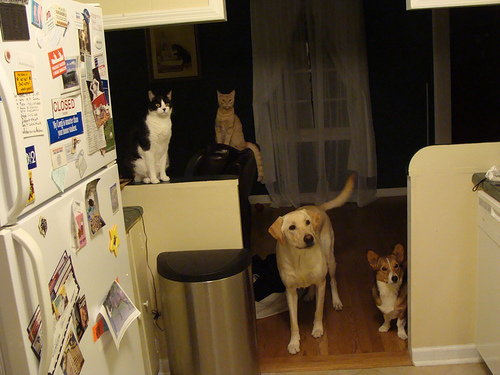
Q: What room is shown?
A: It is a kitchen.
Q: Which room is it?
A: It is a kitchen.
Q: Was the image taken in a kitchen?
A: Yes, it was taken in a kitchen.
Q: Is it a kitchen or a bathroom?
A: It is a kitchen.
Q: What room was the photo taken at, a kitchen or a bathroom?
A: It was taken at a kitchen.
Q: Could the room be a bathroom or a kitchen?
A: It is a kitchen.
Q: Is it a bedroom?
A: No, it is a kitchen.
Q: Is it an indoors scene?
A: Yes, it is indoors.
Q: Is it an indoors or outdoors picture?
A: It is indoors.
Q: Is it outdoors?
A: No, it is indoors.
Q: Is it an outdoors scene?
A: No, it is indoors.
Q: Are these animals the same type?
A: No, there are both dogs and cats.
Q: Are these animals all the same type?
A: No, there are both dogs and cats.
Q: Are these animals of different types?
A: Yes, they are dogs and cats.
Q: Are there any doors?
A: Yes, there is a door.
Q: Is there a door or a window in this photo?
A: Yes, there is a door.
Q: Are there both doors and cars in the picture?
A: No, there is a door but no cars.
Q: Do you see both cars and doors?
A: No, there is a door but no cars.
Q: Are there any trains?
A: No, there are no trains.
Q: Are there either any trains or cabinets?
A: No, there are no trains or cabinets.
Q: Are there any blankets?
A: No, there are no blankets.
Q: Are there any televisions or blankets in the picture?
A: No, there are no blankets or televisions.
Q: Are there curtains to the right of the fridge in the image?
A: Yes, there are curtains to the right of the fridge.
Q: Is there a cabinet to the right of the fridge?
A: No, there are curtains to the right of the fridge.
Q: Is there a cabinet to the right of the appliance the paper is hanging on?
A: No, there are curtains to the right of the fridge.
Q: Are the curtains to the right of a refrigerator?
A: Yes, the curtains are to the right of a refrigerator.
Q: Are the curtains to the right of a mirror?
A: No, the curtains are to the right of a refrigerator.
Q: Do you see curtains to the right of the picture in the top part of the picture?
A: Yes, there are curtains to the right of the picture.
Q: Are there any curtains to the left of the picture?
A: No, the curtains are to the right of the picture.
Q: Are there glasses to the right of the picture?
A: No, there are curtains to the right of the picture.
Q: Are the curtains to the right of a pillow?
A: No, the curtains are to the right of the picture.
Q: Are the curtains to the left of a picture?
A: No, the curtains are to the right of a picture.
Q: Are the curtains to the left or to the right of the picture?
A: The curtains are to the right of the picture.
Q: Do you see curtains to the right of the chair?
A: Yes, there are curtains to the right of the chair.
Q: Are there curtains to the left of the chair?
A: No, the curtains are to the right of the chair.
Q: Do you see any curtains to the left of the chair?
A: No, the curtains are to the right of the chair.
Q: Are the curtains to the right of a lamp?
A: No, the curtains are to the right of a chair.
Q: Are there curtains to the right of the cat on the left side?
A: Yes, there are curtains to the right of the cat.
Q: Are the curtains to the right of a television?
A: No, the curtains are to the right of a cat.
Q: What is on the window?
A: The curtains are on the window.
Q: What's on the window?
A: The curtains are on the window.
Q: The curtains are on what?
A: The curtains are on the window.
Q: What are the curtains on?
A: The curtains are on the window.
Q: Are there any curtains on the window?
A: Yes, there are curtains on the window.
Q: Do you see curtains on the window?
A: Yes, there are curtains on the window.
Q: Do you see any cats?
A: Yes, there is a cat.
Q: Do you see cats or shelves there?
A: Yes, there is a cat.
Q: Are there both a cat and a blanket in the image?
A: No, there is a cat but no blankets.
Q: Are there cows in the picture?
A: No, there are no cows.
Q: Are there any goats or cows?
A: No, there are no cows or goats.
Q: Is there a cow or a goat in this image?
A: No, there are no cows or goats.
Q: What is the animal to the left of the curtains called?
A: The animal is a cat.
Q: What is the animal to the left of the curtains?
A: The animal is a cat.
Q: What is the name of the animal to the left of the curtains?
A: The animal is a cat.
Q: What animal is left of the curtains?
A: The animal is a cat.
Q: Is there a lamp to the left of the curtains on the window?
A: No, there is a cat to the left of the curtains.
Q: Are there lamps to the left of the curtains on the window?
A: No, there is a cat to the left of the curtains.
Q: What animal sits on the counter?
A: The cat sits on the counter.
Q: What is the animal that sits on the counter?
A: The animal is a cat.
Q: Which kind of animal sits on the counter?
A: The animal is a cat.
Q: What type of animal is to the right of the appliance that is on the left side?
A: The animal is a cat.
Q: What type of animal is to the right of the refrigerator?
A: The animal is a cat.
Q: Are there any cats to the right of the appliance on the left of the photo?
A: Yes, there is a cat to the right of the fridge.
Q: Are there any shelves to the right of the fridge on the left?
A: No, there is a cat to the right of the freezer.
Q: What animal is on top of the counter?
A: The animal is a cat.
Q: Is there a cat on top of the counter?
A: Yes, there is a cat on top of the counter.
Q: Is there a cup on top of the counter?
A: No, there is a cat on top of the counter.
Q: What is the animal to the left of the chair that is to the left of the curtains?
A: The animal is a cat.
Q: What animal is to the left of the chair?
A: The animal is a cat.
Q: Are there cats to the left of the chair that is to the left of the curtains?
A: Yes, there is a cat to the left of the chair.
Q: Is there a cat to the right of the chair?
A: No, the cat is to the left of the chair.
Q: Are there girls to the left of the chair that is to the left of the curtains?
A: No, there is a cat to the left of the chair.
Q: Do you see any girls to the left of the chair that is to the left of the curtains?
A: No, there is a cat to the left of the chair.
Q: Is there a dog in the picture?
A: Yes, there is a dog.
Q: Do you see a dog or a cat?
A: Yes, there is a dog.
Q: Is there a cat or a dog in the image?
A: Yes, there is a dog.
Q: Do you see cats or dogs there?
A: Yes, there is a dog.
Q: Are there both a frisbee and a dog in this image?
A: No, there is a dog but no frisbees.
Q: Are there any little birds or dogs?
A: Yes, there is a little dog.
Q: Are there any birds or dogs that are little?
A: Yes, the dog is little.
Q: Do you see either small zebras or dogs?
A: Yes, there is a small dog.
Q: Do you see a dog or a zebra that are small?
A: Yes, the dog is small.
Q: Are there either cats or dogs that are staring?
A: Yes, the dog is staring.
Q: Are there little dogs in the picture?
A: Yes, there is a little dog.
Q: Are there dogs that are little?
A: Yes, there is a dog that is little.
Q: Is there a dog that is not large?
A: Yes, there is a little dog.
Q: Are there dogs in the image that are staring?
A: Yes, there is a dog that is staring.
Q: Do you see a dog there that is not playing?
A: Yes, there is a dog that is staring .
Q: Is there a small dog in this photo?
A: Yes, there is a small dog.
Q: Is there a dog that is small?
A: Yes, there is a dog that is small.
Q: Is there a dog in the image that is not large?
A: Yes, there is a small dog.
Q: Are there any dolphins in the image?
A: No, there are no dolphins.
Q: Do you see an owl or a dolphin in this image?
A: No, there are no dolphins or owls.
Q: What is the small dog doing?
A: The dog is staring.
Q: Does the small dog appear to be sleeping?
A: No, the dog is staring.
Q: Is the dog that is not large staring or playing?
A: The dog is staring.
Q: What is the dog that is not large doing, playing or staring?
A: The dog is staring.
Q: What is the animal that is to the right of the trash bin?
A: The animal is a dog.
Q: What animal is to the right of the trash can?
A: The animal is a dog.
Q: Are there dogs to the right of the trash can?
A: Yes, there is a dog to the right of the trash can.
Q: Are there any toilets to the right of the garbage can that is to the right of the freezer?
A: No, there is a dog to the right of the garbage bin.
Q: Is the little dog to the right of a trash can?
A: Yes, the dog is to the right of a trash can.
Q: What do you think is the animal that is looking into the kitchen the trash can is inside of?
A: The animal is a dog.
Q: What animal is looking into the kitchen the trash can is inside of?
A: The animal is a dog.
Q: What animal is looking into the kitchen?
A: The animal is a dog.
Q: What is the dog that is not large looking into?
A: The dog is looking into the kitchen.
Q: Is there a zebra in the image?
A: No, there are no zebras.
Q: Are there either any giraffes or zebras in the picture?
A: No, there are no zebras or giraffes.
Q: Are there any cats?
A: Yes, there is a cat.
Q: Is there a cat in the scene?
A: Yes, there is a cat.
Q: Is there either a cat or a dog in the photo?
A: Yes, there is a cat.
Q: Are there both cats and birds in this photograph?
A: No, there is a cat but no birds.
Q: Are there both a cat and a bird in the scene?
A: No, there is a cat but no birds.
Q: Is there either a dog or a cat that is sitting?
A: Yes, the cat is sitting.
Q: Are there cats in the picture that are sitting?
A: Yes, there is a cat that is sitting.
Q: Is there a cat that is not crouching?
A: Yes, there is a cat that is sitting.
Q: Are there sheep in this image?
A: No, there are no sheep.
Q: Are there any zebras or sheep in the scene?
A: No, there are no sheep or zebras.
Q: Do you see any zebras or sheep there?
A: No, there are no sheep or zebras.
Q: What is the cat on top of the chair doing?
A: The cat is sitting.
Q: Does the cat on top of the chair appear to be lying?
A: No, the cat is sitting.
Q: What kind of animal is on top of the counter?
A: The animal is a cat.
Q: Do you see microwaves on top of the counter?
A: No, there is a cat on top of the counter.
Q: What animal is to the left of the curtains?
A: The animal is a cat.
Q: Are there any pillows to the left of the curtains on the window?
A: No, there is a cat to the left of the curtains.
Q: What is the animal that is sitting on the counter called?
A: The animal is a cat.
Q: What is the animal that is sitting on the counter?
A: The animal is a cat.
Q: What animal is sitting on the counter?
A: The animal is a cat.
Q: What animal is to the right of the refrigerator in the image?
A: The animal is a cat.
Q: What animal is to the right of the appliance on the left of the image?
A: The animal is a cat.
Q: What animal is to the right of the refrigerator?
A: The animal is a cat.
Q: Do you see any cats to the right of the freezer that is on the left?
A: Yes, there is a cat to the right of the fridge.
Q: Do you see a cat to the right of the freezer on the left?
A: Yes, there is a cat to the right of the fridge.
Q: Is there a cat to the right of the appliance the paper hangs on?
A: Yes, there is a cat to the right of the fridge.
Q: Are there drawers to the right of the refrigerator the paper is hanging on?
A: No, there is a cat to the right of the freezer.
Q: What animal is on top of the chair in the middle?
A: The cat is on top of the chair.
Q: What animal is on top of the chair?
A: The animal is a cat.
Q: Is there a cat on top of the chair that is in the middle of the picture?
A: Yes, there is a cat on top of the chair.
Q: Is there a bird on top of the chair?
A: No, there is a cat on top of the chair.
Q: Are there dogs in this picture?
A: Yes, there is a dog.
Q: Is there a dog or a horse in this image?
A: Yes, there is a dog.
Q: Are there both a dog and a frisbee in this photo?
A: No, there is a dog but no frisbees.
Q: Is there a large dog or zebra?
A: Yes, there is a large dog.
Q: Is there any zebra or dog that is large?
A: Yes, the dog is large.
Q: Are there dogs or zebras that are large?
A: Yes, the dog is large.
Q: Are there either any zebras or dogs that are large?
A: Yes, the dog is large.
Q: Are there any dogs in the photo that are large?
A: Yes, there is a large dog.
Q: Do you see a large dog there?
A: Yes, there is a large dog.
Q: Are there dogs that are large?
A: Yes, there is a dog that is large.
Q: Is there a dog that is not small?
A: Yes, there is a large dog.